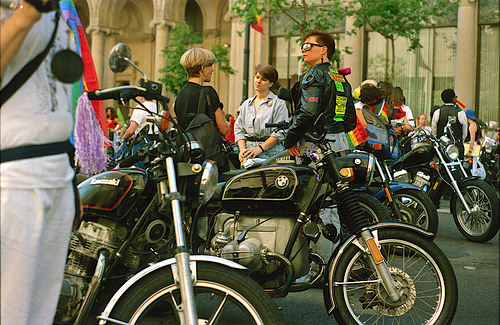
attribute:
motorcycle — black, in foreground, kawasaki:
[79, 132, 446, 313]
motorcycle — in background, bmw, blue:
[241, 147, 434, 236]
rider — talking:
[295, 35, 356, 285]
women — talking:
[178, 49, 289, 176]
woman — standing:
[293, 37, 347, 153]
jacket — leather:
[282, 71, 357, 144]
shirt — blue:
[234, 93, 284, 152]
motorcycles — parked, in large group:
[91, 85, 493, 302]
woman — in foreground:
[6, 11, 110, 315]